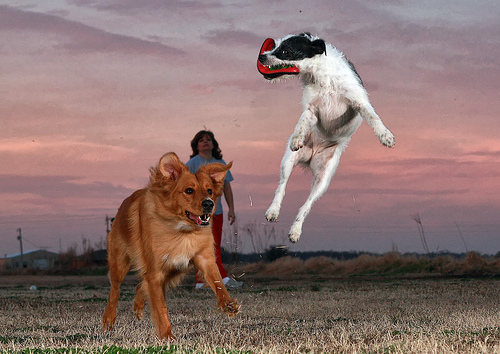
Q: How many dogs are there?
A: 2.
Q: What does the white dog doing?
A: Playing fetch.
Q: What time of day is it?
A: Evening.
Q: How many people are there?
A: 1.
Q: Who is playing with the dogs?
A: A woman.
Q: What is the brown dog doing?
A: Running.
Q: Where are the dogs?
A: In a field.